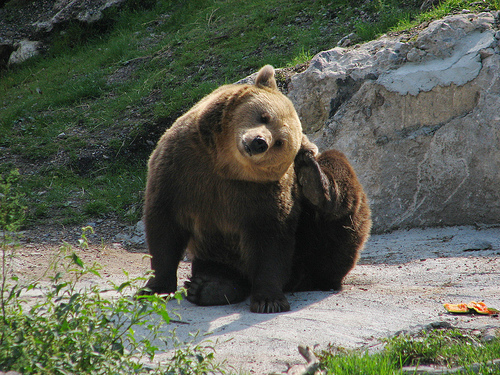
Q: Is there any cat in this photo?
A: No, there are no cats.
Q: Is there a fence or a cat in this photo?
A: No, there are no cats or fences.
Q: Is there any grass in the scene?
A: Yes, there is grass.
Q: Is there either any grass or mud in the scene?
A: Yes, there is grass.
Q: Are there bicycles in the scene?
A: No, there are no bicycles.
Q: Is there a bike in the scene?
A: No, there are no bikes.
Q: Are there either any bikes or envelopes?
A: No, there are no bikes or envelopes.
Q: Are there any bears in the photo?
A: Yes, there is a bear.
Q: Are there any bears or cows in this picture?
A: Yes, there is a bear.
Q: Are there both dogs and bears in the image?
A: No, there is a bear but no dogs.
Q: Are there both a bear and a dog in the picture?
A: No, there is a bear but no dogs.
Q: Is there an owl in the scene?
A: No, there are no owls.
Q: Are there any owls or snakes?
A: No, there are no owls or snakes.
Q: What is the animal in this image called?
A: The animal is a bear.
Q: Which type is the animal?
A: The animal is a bear.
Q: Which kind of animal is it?
A: The animal is a bear.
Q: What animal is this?
A: This is a bear.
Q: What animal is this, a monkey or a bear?
A: This is a bear.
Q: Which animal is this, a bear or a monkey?
A: This is a bear.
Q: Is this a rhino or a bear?
A: This is a bear.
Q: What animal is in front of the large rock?
A: The bear is in front of the rock.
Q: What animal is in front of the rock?
A: The bear is in front of the rock.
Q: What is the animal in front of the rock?
A: The animal is a bear.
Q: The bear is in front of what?
A: The bear is in front of the rock.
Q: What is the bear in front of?
A: The bear is in front of the rock.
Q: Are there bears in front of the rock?
A: Yes, there is a bear in front of the rock.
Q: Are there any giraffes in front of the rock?
A: No, there is a bear in front of the rock.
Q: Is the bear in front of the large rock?
A: Yes, the bear is in front of the rock.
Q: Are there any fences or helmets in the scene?
A: No, there are no fences or helmets.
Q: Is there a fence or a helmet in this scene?
A: No, there are no fences or helmets.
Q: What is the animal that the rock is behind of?
A: The animal is a bear.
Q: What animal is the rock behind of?
A: The rock is behind the bear.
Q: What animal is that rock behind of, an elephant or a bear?
A: The rock is behind a bear.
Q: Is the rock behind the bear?
A: Yes, the rock is behind the bear.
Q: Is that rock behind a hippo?
A: No, the rock is behind the bear.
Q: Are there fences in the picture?
A: No, there are no fences.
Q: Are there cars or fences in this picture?
A: No, there are no fences or cars.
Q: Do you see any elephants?
A: No, there are no elephants.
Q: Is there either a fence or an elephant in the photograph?
A: No, there are no elephants or fences.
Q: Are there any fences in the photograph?
A: No, there are no fences.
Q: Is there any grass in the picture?
A: Yes, there is grass.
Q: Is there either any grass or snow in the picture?
A: Yes, there is grass.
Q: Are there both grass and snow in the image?
A: No, there is grass but no snow.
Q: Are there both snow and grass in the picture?
A: No, there is grass but no snow.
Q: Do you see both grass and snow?
A: No, there is grass but no snow.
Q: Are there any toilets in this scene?
A: No, there are no toilets.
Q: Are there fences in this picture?
A: No, there are no fences.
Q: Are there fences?
A: No, there are no fences.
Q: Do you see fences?
A: No, there are no fences.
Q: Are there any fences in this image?
A: No, there are no fences.